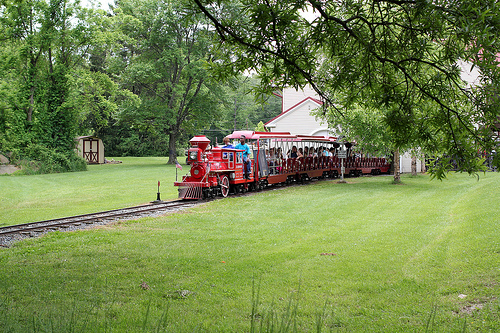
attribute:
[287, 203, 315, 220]
grass — green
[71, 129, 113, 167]
shed — white